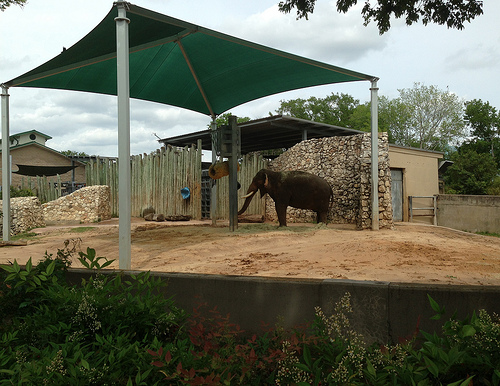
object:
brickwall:
[0, 264, 500, 349]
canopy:
[0, 0, 380, 273]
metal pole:
[371, 76, 379, 231]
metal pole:
[212, 115, 217, 225]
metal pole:
[0, 85, 10, 241]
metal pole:
[116, 1, 130, 269]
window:
[29, 134, 36, 141]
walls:
[266, 131, 392, 230]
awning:
[0, 0, 379, 269]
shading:
[27, 222, 373, 271]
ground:
[0, 216, 500, 285]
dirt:
[0, 216, 500, 285]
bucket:
[181, 187, 191, 200]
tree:
[277, 0, 484, 35]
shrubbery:
[0, 237, 500, 385]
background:
[0, 0, 500, 386]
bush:
[0, 238, 500, 386]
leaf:
[427, 293, 441, 313]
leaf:
[419, 342, 442, 364]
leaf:
[81, 246, 96, 262]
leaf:
[33, 275, 48, 286]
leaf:
[458, 325, 477, 340]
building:
[0, 112, 444, 231]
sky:
[0, 0, 499, 163]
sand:
[128, 221, 500, 285]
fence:
[20, 140, 204, 221]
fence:
[215, 153, 267, 220]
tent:
[1, 0, 376, 120]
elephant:
[238, 168, 334, 227]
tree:
[208, 81, 500, 195]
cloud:
[0, 0, 500, 159]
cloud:
[69, 110, 126, 127]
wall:
[0, 195, 44, 236]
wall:
[40, 184, 110, 221]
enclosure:
[0, 194, 500, 346]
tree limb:
[18, 138, 268, 221]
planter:
[0, 236, 500, 385]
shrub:
[0, 235, 500, 386]